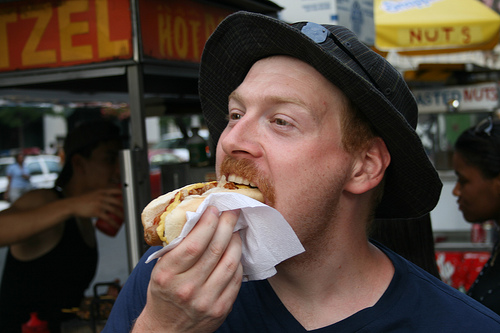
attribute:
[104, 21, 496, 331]
man — light-skinned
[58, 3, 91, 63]
e — letter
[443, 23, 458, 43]
t — letter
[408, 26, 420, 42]
n — letter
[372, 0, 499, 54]
cover — yellow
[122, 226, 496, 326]
shirt — t-shirt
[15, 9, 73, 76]
z — letter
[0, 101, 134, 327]
woman — underneath